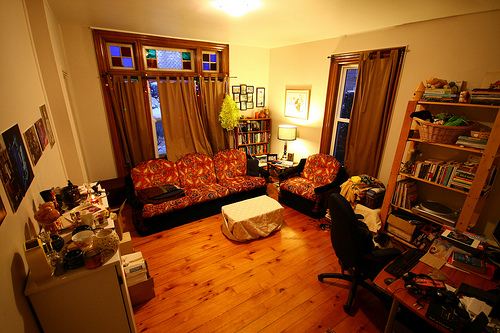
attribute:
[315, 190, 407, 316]
chair — black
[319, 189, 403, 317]
computer chair — black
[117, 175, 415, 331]
floor — wooden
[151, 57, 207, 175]
drapes — Brown 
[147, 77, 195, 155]
window — open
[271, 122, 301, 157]
lamp — Small 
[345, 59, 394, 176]
curtain — brown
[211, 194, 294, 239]
table — centered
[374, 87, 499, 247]
shelves — cluttered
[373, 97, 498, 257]
bookshelf — wooden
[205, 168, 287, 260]
cloth — white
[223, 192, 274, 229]
table — Small 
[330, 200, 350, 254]
chair — black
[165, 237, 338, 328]
wood floor — wooden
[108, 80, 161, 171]
curtain — brown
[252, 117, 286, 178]
bookcase — Small 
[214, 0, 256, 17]
light — on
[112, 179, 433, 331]
wood — brown 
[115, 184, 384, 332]
flooring — wooden